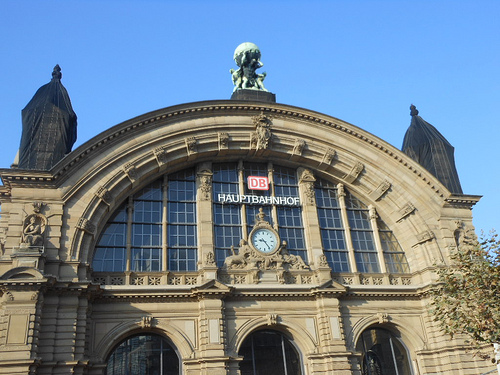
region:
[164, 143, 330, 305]
the clock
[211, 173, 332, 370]
the clock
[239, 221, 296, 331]
the clock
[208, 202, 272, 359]
the clock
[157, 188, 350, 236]
beautiful old building with the letter h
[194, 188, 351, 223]
beautiful old building with the letter a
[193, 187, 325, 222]
beautiful old building with the letter u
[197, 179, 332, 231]
beautiful old building with the letter p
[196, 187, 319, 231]
beautiful old building with the letter t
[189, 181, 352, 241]
beautiful old building with the letter b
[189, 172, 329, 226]
beautiful old building with the letter n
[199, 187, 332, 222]
beautiful old building with the letter o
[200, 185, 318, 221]
beautiful old building with the letter f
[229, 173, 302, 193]
beautiful old building with the letter d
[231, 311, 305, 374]
an arched opening in a building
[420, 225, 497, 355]
a tree outside a building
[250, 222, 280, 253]
a clock on the front of a building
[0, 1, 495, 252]
a blue sky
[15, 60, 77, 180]
a black covered dome on a building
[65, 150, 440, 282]
a huge arched window on the front of a building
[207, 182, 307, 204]
a name in the window of a building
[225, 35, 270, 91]
a green statue on top of a building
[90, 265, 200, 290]
a concrete railing below a window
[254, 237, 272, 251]
the black hands on a clock face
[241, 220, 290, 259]
A clock is on the building.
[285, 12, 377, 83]
The sky is blue.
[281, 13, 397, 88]
The sky is clear.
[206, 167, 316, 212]
A name is on the building.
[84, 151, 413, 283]
The building has large windows.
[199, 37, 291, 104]
A statue is on the top of the building.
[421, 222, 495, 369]
A tree is to the right in the picture.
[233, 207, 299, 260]
The clock face is white.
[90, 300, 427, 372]
The building has large doors.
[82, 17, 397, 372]
The building is large.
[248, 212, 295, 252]
a white clock in middle of building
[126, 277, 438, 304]
some triangles and ripples in architect of building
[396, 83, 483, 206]
a tower on building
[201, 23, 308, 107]
a gargoyle on top of building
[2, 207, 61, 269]
a statue on building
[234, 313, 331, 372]
an arch doorway on building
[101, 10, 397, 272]
an arch windown on building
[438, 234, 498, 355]
a green tree next to building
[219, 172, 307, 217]
red and white branding and name on building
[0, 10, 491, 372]
brick building with clock and towers